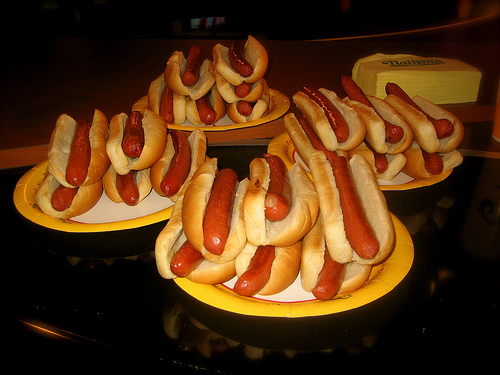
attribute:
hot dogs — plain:
[181, 164, 232, 284]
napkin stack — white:
[351, 50, 481, 105]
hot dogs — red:
[208, 167, 238, 254]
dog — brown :
[327, 160, 389, 266]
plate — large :
[168, 132, 423, 323]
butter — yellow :
[350, 51, 483, 106]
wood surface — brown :
[25, 39, 498, 181]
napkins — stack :
[346, 49, 483, 109]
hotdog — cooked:
[308, 149, 397, 266]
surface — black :
[0, 140, 498, 373]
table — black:
[20, 105, 488, 339]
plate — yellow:
[165, 190, 414, 320]